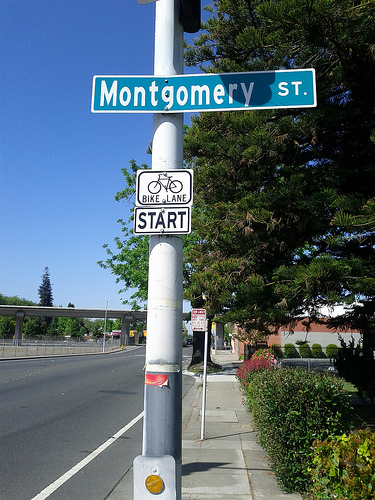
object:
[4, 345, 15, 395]
street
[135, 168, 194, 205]
sign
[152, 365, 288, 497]
sidewalk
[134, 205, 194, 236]
sign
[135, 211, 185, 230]
start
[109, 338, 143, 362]
street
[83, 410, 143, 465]
line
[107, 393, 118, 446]
street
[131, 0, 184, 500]
metal pole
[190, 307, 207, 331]
sign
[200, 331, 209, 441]
pole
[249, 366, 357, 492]
hedge bush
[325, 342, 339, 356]
hedge bush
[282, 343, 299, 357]
hedge bush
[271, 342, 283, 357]
hedge bush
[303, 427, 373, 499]
hedge bush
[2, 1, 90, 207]
sky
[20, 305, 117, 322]
overpass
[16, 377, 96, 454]
road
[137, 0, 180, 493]
pole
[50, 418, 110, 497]
lane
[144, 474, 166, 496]
dot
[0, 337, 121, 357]
fence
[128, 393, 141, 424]
street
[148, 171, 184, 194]
bicycle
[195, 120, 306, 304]
green leaves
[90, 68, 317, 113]
sign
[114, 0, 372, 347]
tree